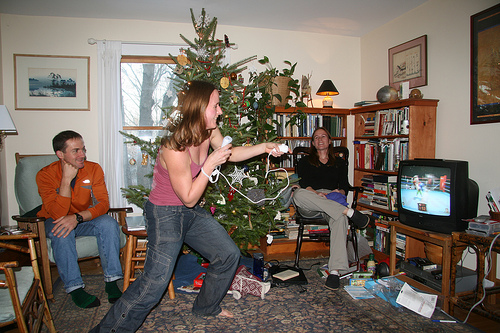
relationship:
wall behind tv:
[361, 0, 500, 280] [396, 157, 479, 235]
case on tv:
[396, 158, 479, 233] [396, 157, 479, 235]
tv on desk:
[396, 157, 479, 235] [387, 220, 495, 312]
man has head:
[36, 130, 126, 306] [53, 130, 87, 169]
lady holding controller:
[87, 80, 292, 332] [202, 134, 292, 204]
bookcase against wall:
[262, 99, 438, 262] [1, 0, 499, 276]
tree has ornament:
[117, 7, 292, 261] [220, 75, 229, 90]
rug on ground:
[41, 258, 478, 332] [0, 252, 498, 331]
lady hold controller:
[87, 80, 292, 332] [202, 134, 292, 204]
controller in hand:
[202, 134, 292, 204] [268, 143, 289, 159]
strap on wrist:
[199, 167, 212, 179] [203, 155, 215, 184]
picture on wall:
[388, 33, 430, 94] [361, 0, 500, 280]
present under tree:
[232, 265, 275, 299] [117, 7, 292, 261]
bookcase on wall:
[262, 99, 438, 262] [1, 0, 499, 276]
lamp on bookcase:
[316, 78, 340, 110] [262, 99, 438, 262]